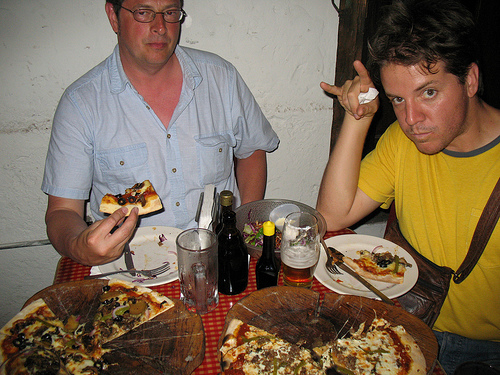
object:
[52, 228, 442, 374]
table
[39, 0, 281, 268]
man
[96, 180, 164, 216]
pizza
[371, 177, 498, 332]
bag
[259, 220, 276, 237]
cap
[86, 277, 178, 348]
pizza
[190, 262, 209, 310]
handle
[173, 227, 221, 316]
glass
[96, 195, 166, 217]
crust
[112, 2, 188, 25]
glasses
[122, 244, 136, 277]
knife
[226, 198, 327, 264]
bowl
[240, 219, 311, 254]
salad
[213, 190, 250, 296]
beer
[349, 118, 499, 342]
shirt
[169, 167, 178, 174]
button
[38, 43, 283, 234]
shirt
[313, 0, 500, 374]
man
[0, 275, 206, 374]
wooden tray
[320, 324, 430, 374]
pizza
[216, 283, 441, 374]
pizza tray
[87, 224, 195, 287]
white plate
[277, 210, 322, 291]
glass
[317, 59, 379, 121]
hand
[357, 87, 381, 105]
napkin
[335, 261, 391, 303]
knife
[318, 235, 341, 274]
fork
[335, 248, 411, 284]
pizza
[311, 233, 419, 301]
plate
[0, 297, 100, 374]
pizza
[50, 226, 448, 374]
table cloth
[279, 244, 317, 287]
beer